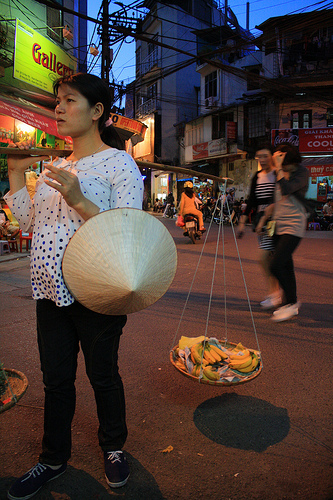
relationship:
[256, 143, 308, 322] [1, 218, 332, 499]
person walking on street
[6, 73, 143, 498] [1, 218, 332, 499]
woman walking on street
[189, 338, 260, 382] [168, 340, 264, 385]
bananas on top of tray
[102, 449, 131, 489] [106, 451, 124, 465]
shoe has laces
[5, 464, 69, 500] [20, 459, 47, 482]
shoe has laces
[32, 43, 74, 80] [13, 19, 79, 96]
writing printed on sign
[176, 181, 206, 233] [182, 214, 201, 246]
person riding motorcycle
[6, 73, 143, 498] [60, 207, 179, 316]
woman carrying hat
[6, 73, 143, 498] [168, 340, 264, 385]
woman carrying tray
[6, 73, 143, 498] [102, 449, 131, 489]
woman wearing shoe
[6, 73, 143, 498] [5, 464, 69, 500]
woman wearing shoe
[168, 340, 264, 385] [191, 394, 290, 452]
tray casting shadow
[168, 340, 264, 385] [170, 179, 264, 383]
tray suspended from chains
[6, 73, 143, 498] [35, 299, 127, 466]
woman wearing pants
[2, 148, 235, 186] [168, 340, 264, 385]
pole connected to tray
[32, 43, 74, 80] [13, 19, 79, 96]
writing on surface of sign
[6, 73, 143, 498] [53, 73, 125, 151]
woman has hair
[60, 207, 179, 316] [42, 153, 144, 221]
hat hanging on arm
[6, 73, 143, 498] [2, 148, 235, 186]
woman carrying pole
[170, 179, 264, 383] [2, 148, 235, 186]
chains attached to pole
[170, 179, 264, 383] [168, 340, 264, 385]
chains suspend tray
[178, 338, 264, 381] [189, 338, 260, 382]
towel under bananas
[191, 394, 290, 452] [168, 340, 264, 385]
shadow under tray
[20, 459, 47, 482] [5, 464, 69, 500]
laces tied to shoe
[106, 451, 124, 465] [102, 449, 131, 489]
laces tied to shoe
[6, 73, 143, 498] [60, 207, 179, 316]
woman holding hat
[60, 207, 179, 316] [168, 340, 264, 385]
hat to left of tray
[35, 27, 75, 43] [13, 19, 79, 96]
light above sign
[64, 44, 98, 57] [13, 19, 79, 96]
light above sign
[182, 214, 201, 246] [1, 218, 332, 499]
motorcycle on top of street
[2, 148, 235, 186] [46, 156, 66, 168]
pole on top of shoulder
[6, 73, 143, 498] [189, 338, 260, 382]
woman carrying bananas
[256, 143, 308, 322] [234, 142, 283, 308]
person walking next to woman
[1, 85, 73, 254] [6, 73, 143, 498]
restaurant behind woman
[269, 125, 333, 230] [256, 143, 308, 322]
shop behind person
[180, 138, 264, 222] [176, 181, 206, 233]
shop behind person